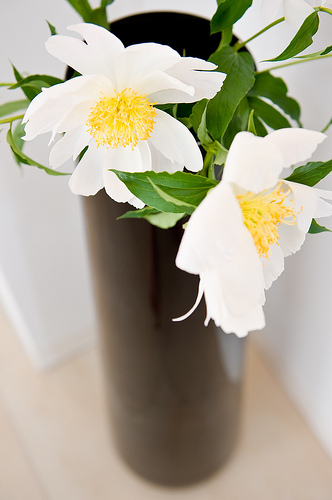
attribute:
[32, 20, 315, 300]
petals — white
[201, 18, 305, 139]
leaves — green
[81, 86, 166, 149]
stamens — orange, yellow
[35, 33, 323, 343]
flowers — white, facing, spreading, lovely, large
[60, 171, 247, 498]
vase — oval, dark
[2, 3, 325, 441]
wall — beige